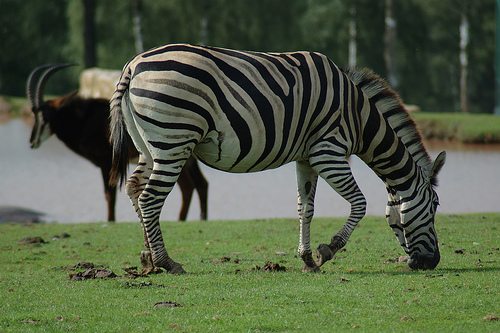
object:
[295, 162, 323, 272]
leg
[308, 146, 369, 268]
leg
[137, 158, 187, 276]
leg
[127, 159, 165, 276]
leg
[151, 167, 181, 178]
stripe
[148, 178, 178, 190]
stripe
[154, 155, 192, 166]
stripe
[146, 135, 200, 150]
stripe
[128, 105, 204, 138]
stripe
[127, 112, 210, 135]
stripe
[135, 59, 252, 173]
stripe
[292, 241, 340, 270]
hoves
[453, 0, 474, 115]
tree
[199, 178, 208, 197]
knees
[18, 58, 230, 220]
antelope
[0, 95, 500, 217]
water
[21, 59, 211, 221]
antelope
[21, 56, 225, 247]
ram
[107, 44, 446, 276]
zebra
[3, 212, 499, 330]
grass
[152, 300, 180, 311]
indent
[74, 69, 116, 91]
rock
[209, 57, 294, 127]
stripes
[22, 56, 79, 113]
horns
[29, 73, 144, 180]
animal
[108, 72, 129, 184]
tail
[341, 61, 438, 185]
mane fur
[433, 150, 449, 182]
zebra ear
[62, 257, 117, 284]
dirt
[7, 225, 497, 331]
ground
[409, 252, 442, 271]
mouth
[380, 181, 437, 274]
jaw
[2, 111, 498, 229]
lake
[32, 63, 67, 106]
horn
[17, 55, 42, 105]
horn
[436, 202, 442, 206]
eyelash